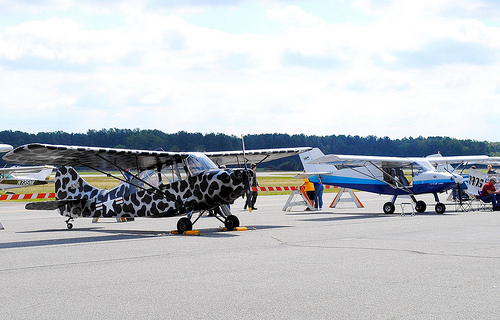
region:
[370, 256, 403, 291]
part of a floor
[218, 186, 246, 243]
part of a wheel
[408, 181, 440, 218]
part of a wheel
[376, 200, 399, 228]
part of a wheel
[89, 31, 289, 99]
sky is blue and white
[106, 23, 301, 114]
puffy clouds in sky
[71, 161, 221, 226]
black and white plane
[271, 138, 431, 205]
blue and white plane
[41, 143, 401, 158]
green trees behind planes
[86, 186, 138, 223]
white star on plane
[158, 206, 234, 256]
black wheels on plane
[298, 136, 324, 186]
white tail on plane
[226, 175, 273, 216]
Zebra print on a wing.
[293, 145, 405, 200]
Zebra print on a wing.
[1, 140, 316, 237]
a giraffe print airplane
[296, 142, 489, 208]
a blue and white airplane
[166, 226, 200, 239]
yellow chocks blocking an airplane wheel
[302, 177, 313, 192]
a yellow shirt on a person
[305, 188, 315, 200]
black shorts on a person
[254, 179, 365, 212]
an orange and white striped barricade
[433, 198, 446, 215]
the nose wheel of an airplane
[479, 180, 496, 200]
a red shirt on a man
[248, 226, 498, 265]
a long crack in the tarmac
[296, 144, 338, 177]
the white tail of an airplane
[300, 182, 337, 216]
Man with orange vest on by plane.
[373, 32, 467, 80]
Man with orange vest on by plane.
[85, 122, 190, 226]
Man with orange vest on by plane.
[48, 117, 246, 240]
spotted blue plane near airstrip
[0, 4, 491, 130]
white clouds in the sky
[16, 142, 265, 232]
a small black and white airplane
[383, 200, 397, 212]
a black wheel on the airplane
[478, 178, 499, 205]
a man sitting in a chair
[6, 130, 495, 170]
trees behind the airplanes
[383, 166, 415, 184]
the door on the airplane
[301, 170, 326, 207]
people standing behind the airplane